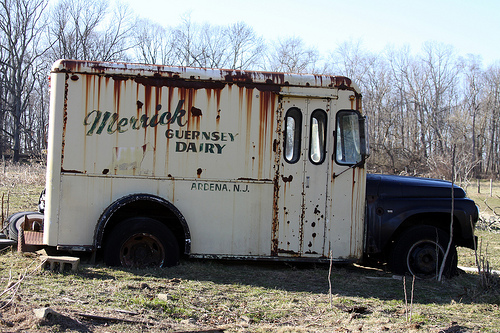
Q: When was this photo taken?
A: During the day.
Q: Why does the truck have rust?
A: It is old.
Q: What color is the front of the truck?
A: Black.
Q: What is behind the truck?
A: Trees.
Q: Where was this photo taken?
A: Outside on the grass.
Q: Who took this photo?
A: A person visiting the area.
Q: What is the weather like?
A: Sunny.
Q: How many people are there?
A: None.